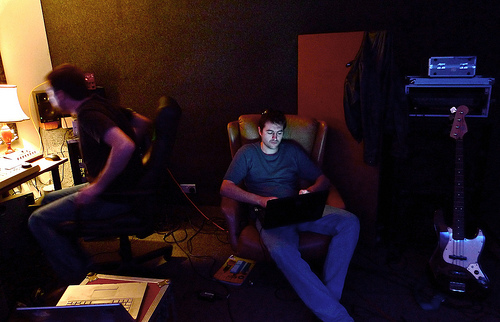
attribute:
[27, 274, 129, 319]
laptop — silver, open